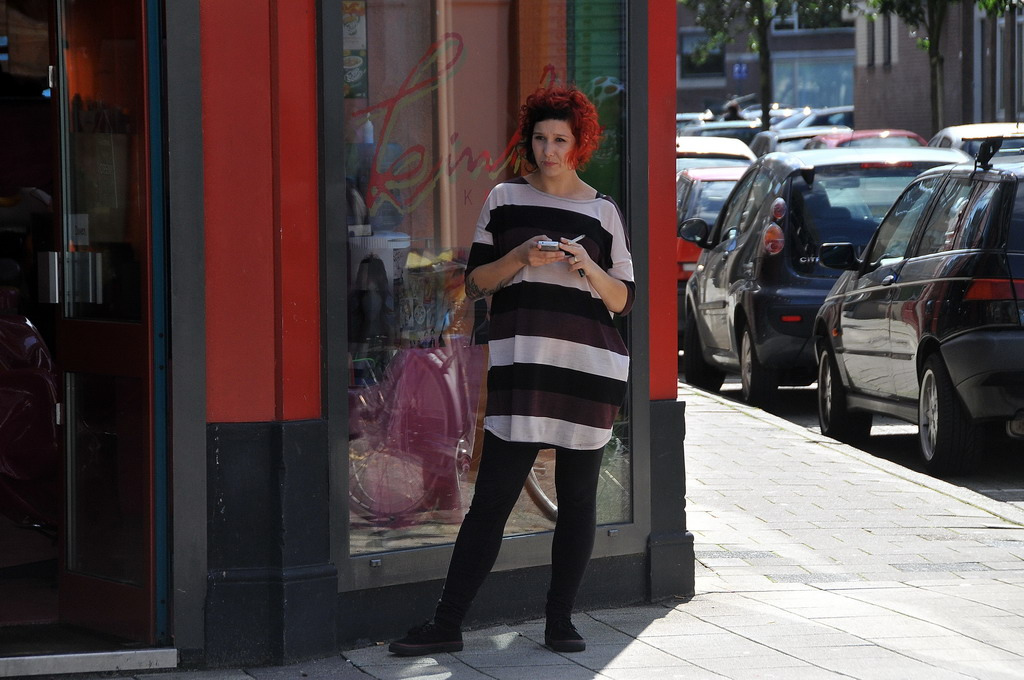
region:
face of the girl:
[479, 60, 631, 223]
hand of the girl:
[483, 179, 629, 317]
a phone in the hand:
[422, 183, 664, 342]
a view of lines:
[730, 538, 833, 646]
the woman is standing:
[381, 64, 637, 656]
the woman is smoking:
[381, 52, 625, 651]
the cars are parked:
[677, 127, 1020, 444]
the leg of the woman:
[379, 424, 534, 660]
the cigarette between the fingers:
[552, 232, 592, 258]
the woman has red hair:
[394, 48, 661, 666]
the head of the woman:
[500, 85, 615, 194]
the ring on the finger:
[563, 248, 580, 267]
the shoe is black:
[378, 614, 487, 666]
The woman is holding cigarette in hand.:
[528, 225, 592, 265]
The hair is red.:
[550, 82, 596, 146]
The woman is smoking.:
[482, 97, 645, 453]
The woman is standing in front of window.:
[420, 80, 676, 581]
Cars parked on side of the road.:
[702, 156, 1010, 420]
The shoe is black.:
[395, 626, 479, 668]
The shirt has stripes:
[470, 203, 629, 438]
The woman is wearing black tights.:
[452, 412, 617, 608]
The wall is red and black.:
[205, 26, 317, 627]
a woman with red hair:
[526, 74, 616, 164]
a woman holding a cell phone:
[529, 226, 564, 265]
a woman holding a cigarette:
[560, 221, 592, 261]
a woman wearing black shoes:
[392, 586, 481, 662]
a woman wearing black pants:
[449, 427, 624, 637]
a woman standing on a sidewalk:
[379, 67, 664, 668]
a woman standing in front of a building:
[400, 45, 661, 657]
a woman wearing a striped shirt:
[488, 175, 619, 452]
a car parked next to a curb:
[806, 137, 1012, 492]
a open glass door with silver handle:
[20, 27, 147, 654]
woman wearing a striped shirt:
[451, 133, 649, 479]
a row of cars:
[661, 63, 1022, 415]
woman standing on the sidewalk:
[320, 60, 691, 677]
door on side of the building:
[19, 19, 174, 668]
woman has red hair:
[502, 78, 610, 181]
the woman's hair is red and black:
[514, 86, 601, 179]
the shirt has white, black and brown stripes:
[466, 173, 638, 458]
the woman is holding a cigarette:
[512, 86, 602, 263]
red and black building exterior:
[197, 2, 331, 651]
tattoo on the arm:
[465, 265, 501, 298]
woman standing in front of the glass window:
[321, 3, 651, 576]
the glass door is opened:
[13, 7, 162, 628]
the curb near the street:
[690, 372, 1022, 531]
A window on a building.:
[340, 1, 639, 558]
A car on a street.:
[815, 133, 1022, 470]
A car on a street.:
[683, 143, 974, 406]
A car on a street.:
[675, 163, 753, 353]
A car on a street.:
[675, 133, 756, 179]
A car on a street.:
[929, 122, 1022, 161]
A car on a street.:
[808, 127, 927, 147]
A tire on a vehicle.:
[815, 334, 872, 437]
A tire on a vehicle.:
[915, 349, 980, 471]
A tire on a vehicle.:
[738, 315, 778, 404]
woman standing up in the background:
[319, 40, 964, 667]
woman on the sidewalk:
[287, 92, 895, 666]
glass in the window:
[268, 18, 799, 677]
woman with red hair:
[387, 22, 723, 642]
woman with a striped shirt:
[379, 40, 781, 666]